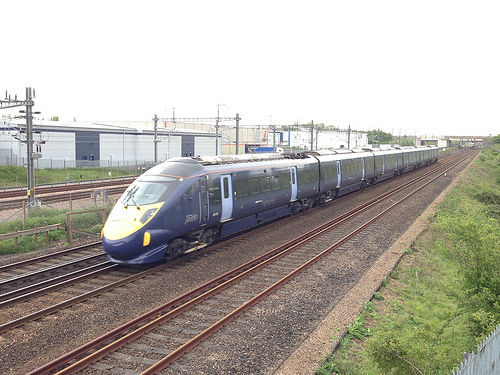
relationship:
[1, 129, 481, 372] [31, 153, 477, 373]
gravel on train track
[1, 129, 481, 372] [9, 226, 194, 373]
gravel on train track